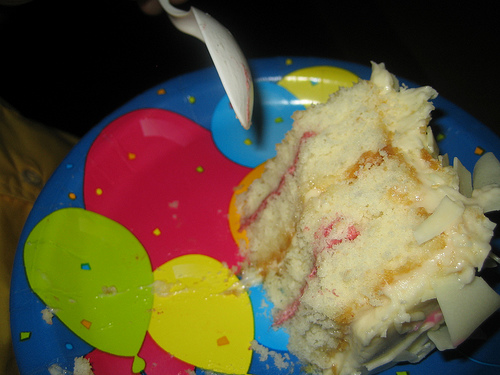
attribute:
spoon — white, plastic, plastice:
[158, 0, 255, 132]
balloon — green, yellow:
[24, 207, 153, 374]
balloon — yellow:
[147, 254, 254, 375]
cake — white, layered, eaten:
[238, 60, 497, 374]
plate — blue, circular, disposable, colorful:
[9, 58, 500, 375]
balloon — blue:
[211, 82, 306, 170]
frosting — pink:
[237, 130, 464, 349]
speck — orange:
[216, 335, 231, 346]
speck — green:
[20, 332, 31, 341]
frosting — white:
[329, 59, 496, 374]